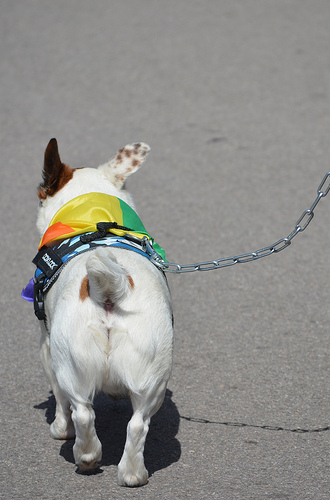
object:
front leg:
[48, 329, 78, 428]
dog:
[34, 137, 174, 485]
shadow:
[176, 412, 329, 440]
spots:
[131, 157, 139, 166]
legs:
[70, 382, 150, 468]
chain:
[163, 172, 329, 275]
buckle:
[33, 289, 47, 320]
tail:
[84, 249, 132, 308]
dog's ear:
[101, 139, 150, 188]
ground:
[216, 136, 229, 162]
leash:
[22, 233, 166, 320]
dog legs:
[38, 339, 164, 470]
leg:
[123, 381, 163, 480]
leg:
[72, 378, 102, 461]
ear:
[39, 136, 71, 198]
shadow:
[32, 383, 182, 476]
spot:
[119, 140, 141, 174]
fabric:
[20, 193, 167, 301]